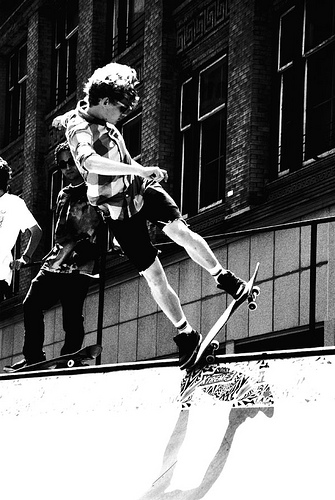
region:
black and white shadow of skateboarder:
[143, 365, 273, 498]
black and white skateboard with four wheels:
[182, 262, 260, 368]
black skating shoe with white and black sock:
[172, 317, 201, 371]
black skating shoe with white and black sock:
[205, 261, 245, 299]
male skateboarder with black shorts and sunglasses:
[52, 63, 248, 369]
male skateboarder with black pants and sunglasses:
[3, 141, 101, 371]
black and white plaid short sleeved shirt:
[63, 100, 150, 219]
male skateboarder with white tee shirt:
[0, 156, 44, 303]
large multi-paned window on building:
[174, 46, 229, 215]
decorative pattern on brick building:
[174, 1, 231, 55]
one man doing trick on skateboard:
[50, 61, 264, 375]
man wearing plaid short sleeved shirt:
[56, 58, 159, 225]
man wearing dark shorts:
[65, 59, 191, 284]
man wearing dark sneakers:
[60, 61, 244, 372]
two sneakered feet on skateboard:
[171, 259, 268, 373]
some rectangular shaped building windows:
[163, 18, 331, 229]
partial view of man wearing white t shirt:
[1, 153, 37, 314]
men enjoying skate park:
[0, 67, 295, 382]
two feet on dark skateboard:
[2, 342, 107, 372]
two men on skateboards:
[46, 60, 261, 365]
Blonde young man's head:
[81, 60, 141, 126]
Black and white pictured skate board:
[182, 260, 261, 371]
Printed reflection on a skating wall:
[170, 357, 333, 408]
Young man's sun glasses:
[111, 96, 133, 114]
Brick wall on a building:
[222, 41, 272, 195]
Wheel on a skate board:
[62, 357, 81, 367]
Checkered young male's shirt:
[66, 113, 149, 218]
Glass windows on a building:
[167, 51, 228, 213]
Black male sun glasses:
[56, 155, 76, 171]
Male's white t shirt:
[0, 190, 37, 286]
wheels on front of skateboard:
[247, 285, 262, 312]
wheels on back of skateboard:
[202, 339, 218, 368]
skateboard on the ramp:
[190, 264, 265, 374]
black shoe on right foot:
[167, 323, 198, 362]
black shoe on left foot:
[208, 268, 251, 295]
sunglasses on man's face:
[58, 157, 78, 169]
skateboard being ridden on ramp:
[4, 343, 107, 377]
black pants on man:
[21, 271, 87, 363]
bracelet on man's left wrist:
[19, 251, 33, 264]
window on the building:
[185, 74, 223, 213]